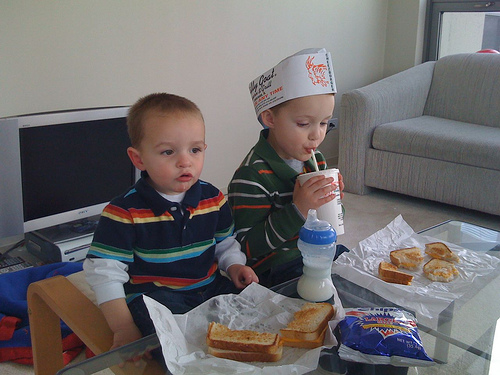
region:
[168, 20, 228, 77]
part of a wall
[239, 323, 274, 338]
part of a bread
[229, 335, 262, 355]
edge of a bread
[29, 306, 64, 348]
edge of a chair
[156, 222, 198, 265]
part of a shirt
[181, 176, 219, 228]
part of a collar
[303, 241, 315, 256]
part of a bottle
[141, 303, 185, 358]
edge of a paper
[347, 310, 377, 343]
part of a food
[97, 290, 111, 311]
edge of a sleeve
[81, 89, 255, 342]
a seated child at a table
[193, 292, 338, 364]
a grilled cheese sandwich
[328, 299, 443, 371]
a bag of potato chips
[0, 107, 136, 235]
a flat screen television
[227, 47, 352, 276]
a child drinking from a straw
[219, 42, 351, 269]
a boy wearing a paper hat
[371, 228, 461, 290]
a cut up grilled cheese sandwich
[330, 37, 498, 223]
a light grey couch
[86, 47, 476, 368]
two little boys eating a meal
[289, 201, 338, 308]
milk in a sippy cup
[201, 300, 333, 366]
grilled cheese sandwich in wrapper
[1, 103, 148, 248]
silver television monitor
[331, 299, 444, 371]
bag of blue and white chips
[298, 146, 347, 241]
white restaurant take out cup with straw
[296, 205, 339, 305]
plastic and blue clear child sip cup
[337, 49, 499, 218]
grey cloth sofa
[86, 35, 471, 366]
two boys eating sandwiches at coffee table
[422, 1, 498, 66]
window in back of gray sofa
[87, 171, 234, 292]
blue collared and striped short sleeve shirt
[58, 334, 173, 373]
corner of glass coffee table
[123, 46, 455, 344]
two little boys eating lunch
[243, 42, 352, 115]
boy wearing a paper hat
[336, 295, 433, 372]
a blue bag of chips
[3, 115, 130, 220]
a silver flat screen TV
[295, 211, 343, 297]
a plastic bottle of milk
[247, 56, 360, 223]
boy drinking through a straw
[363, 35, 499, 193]
gray couch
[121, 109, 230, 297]
little boy wearing a colorful shirt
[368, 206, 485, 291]
four bites of grilled cheese sandwich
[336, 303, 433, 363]
blue and white bag of chips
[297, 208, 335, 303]
sippy cup filled with milk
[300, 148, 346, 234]
paper cup with straw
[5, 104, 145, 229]
tv with silver frame is turned off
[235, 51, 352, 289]
boy wearing paper hat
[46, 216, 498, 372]
glass table top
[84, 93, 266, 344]
little boy wearing a blue striped shirt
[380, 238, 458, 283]
sandwich cut into four pieces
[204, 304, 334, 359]
sandwich cut in half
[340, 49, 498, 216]
white couch